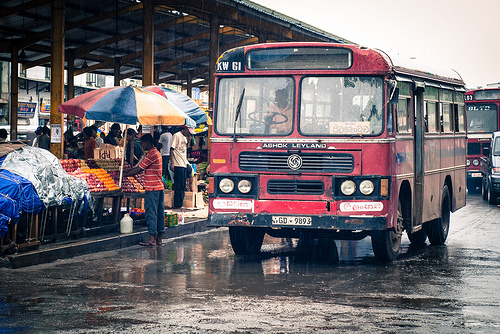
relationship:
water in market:
[2, 202, 492, 331] [4, 0, 247, 272]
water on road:
[83, 229, 330, 294] [4, 197, 494, 331]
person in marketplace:
[80, 125, 100, 162] [2, 0, 362, 257]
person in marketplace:
[103, 120, 126, 147] [2, 0, 362, 257]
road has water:
[1, 214, 500, 334] [160, 239, 336, 328]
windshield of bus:
[215, 74, 384, 134] [195, 35, 471, 269]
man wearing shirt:
[132, 133, 167, 247] [135, 148, 164, 190]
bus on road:
[195, 35, 471, 269] [1, 180, 494, 331]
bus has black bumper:
[195, 35, 471, 269] [204, 213, 387, 233]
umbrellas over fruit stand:
[57, 73, 184, 138] [28, 138, 158, 205]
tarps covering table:
[1, 155, 90, 213] [0, 197, 141, 241]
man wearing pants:
[114, 133, 165, 247] [145, 189, 165, 239]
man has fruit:
[167, 129, 197, 176] [64, 151, 142, 211]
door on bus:
[413, 83, 424, 230] [195, 35, 471, 269]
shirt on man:
[139, 148, 163, 186] [115, 113, 224, 264]